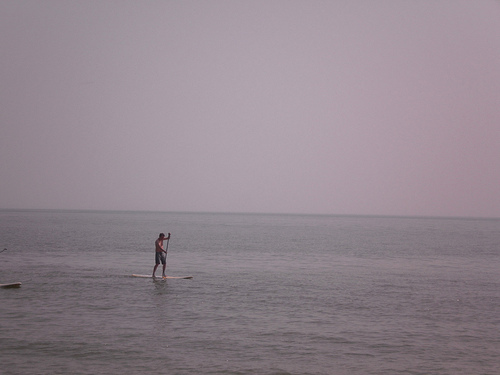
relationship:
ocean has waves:
[19, 209, 496, 372] [94, 289, 343, 333]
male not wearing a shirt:
[152, 231, 172, 278] [147, 239, 175, 256]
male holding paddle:
[152, 231, 172, 278] [164, 233, 175, 274]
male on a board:
[152, 231, 172, 278] [132, 267, 195, 283]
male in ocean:
[152, 231, 172, 278] [19, 209, 496, 372]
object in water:
[2, 272, 28, 292] [7, 252, 98, 337]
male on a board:
[152, 231, 172, 278] [132, 274, 193, 279]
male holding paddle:
[152, 231, 172, 278] [164, 233, 172, 261]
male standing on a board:
[152, 231, 172, 278] [132, 267, 195, 283]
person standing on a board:
[137, 231, 188, 281] [132, 267, 195, 283]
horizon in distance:
[4, 200, 499, 255] [58, 173, 461, 192]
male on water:
[152, 231, 172, 278] [7, 252, 98, 337]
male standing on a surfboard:
[152, 231, 172, 278] [132, 267, 195, 283]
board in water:
[132, 274, 193, 279] [7, 252, 98, 337]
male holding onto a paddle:
[152, 231, 172, 278] [164, 233, 172, 261]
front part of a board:
[174, 273, 194, 283] [132, 274, 193, 279]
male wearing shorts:
[152, 231, 172, 278] [153, 251, 172, 267]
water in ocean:
[7, 252, 98, 337] [19, 209, 496, 372]